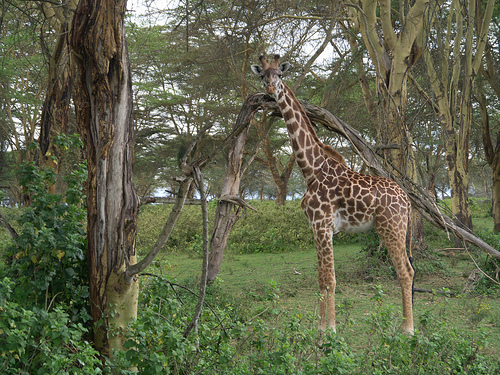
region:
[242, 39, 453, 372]
Giraffe looks at the camera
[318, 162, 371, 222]
Spots are brown and white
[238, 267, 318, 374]
Weeds all over the ground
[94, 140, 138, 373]
bark coming off the trunk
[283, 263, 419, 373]
Giraffe has four legs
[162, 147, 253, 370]
A branch broke off the tree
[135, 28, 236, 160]
The trees are packed together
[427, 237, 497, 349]
Sticks are allover the ground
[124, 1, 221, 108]
The sky has clouds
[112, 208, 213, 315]
Branch sticking off the tree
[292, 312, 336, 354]
part of a plant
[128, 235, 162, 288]
branch of a tree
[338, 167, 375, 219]
stomach of a giraffe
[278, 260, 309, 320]
part of a ground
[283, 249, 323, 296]
part of soem grasss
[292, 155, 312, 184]
edge of a neck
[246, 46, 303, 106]
The giraffe is looking at the camera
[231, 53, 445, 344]
Brown, yellow, and white are the colors here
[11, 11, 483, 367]
This is a forest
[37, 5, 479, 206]
The sky is cloudy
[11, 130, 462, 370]
Bushes are in the front of the image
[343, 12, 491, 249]
This tree is different than the right front tree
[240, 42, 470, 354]
Only animal in the picture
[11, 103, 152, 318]
Fruits in the tree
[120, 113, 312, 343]
Branches are hanging off the tree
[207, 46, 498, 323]
The animal is in front of the falling branch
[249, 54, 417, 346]
one giraffe standing lookin at the camera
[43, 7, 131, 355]
brown thcik stem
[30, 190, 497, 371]
green grass in ground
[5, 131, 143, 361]
green bushes in the left in fornt of stem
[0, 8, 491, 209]
a bunch of trees behinh the giraffe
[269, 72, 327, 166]
long neck of giraffe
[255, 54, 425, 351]
wild animal between bushes and grass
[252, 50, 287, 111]
lonh big head of giraffe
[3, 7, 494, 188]
blue sky behind trees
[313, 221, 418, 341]
large legs of a giraffe standing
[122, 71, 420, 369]
the forest is green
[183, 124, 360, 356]
the forest is green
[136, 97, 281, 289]
the forest is green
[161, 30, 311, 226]
the forest is green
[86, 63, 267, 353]
the forest is green